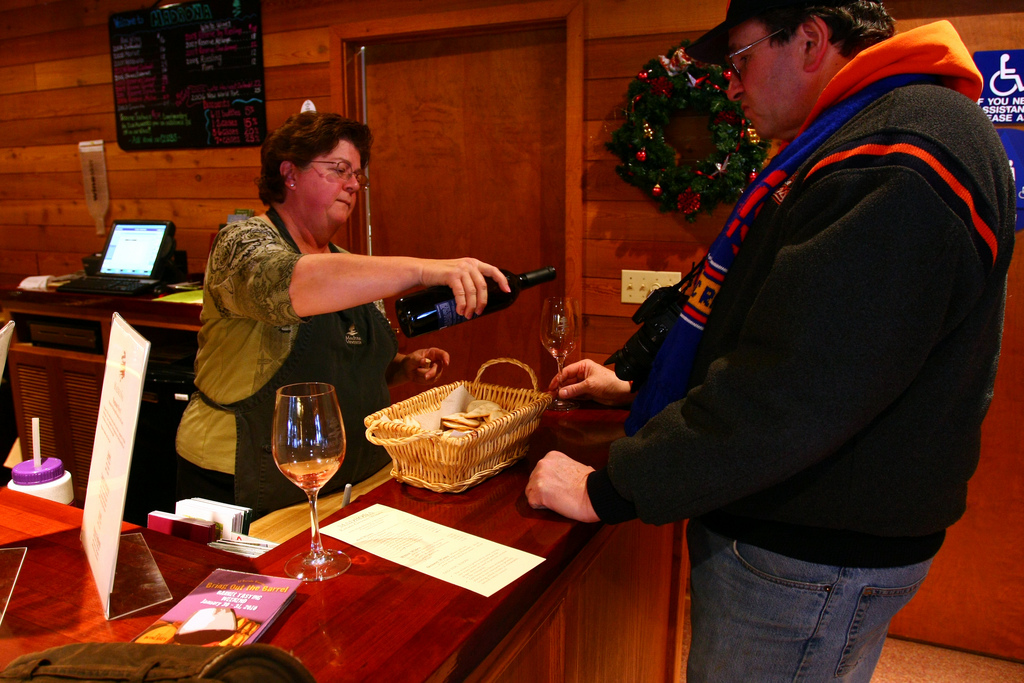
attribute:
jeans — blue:
[669, 533, 932, 673]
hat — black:
[675, 1, 883, 86]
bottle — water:
[10, 308, 949, 414]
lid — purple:
[7, 446, 66, 485]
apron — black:
[182, 223, 423, 508]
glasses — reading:
[690, 35, 755, 83]